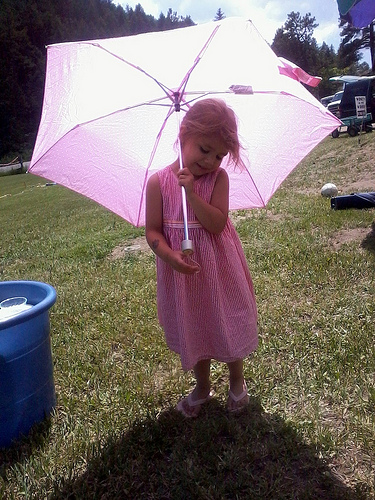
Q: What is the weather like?
A: It is overcast.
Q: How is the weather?
A: It is overcast.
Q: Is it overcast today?
A: Yes, it is overcast.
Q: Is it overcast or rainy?
A: It is overcast.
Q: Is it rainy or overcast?
A: It is overcast.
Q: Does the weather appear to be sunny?
A: No, it is overcast.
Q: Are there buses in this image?
A: No, there are no buses.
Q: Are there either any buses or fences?
A: No, there are no buses or fences.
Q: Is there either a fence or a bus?
A: No, there are no buses or fences.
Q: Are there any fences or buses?
A: No, there are no buses or fences.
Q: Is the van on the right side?
A: Yes, the van is on the right of the image.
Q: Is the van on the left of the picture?
A: No, the van is on the right of the image.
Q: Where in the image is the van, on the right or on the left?
A: The van is on the right of the image.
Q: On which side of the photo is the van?
A: The van is on the right of the image.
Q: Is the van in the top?
A: Yes, the van is in the top of the image.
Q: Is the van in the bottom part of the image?
A: No, the van is in the top of the image.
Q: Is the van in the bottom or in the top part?
A: The van is in the top of the image.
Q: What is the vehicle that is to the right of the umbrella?
A: The vehicle is a van.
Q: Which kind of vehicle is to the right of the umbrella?
A: The vehicle is a van.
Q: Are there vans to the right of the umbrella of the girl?
A: Yes, there is a van to the right of the umbrella.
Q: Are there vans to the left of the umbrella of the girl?
A: No, the van is to the right of the umbrella.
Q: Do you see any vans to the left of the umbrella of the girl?
A: No, the van is to the right of the umbrella.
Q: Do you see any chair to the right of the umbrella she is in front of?
A: No, there is a van to the right of the umbrella.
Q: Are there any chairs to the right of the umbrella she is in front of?
A: No, there is a van to the right of the umbrella.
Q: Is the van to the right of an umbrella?
A: Yes, the van is to the right of an umbrella.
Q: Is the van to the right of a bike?
A: No, the van is to the right of an umbrella.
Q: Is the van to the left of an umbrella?
A: No, the van is to the right of an umbrella.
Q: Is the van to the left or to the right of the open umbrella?
A: The van is to the right of the umbrella.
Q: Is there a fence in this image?
A: No, there are no fences.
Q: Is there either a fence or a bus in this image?
A: No, there are no fences or buses.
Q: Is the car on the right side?
A: Yes, the car is on the right of the image.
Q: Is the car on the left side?
A: No, the car is on the right of the image.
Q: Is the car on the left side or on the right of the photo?
A: The car is on the right of the image.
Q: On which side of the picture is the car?
A: The car is on the right of the image.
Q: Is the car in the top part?
A: Yes, the car is in the top of the image.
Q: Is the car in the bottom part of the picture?
A: No, the car is in the top of the image.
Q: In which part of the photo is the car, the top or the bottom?
A: The car is in the top of the image.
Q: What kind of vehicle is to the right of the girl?
A: The vehicle is a car.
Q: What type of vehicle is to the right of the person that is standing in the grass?
A: The vehicle is a car.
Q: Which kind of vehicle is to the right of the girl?
A: The vehicle is a car.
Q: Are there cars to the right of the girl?
A: Yes, there is a car to the right of the girl.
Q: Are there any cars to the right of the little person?
A: Yes, there is a car to the right of the girl.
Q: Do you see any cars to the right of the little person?
A: Yes, there is a car to the right of the girl.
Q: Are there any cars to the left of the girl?
A: No, the car is to the right of the girl.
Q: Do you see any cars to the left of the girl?
A: No, the car is to the right of the girl.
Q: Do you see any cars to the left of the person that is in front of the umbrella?
A: No, the car is to the right of the girl.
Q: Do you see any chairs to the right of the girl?
A: No, there is a car to the right of the girl.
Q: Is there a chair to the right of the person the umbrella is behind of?
A: No, there is a car to the right of the girl.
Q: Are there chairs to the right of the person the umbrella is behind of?
A: No, there is a car to the right of the girl.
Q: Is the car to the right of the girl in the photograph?
A: Yes, the car is to the right of the girl.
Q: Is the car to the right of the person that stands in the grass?
A: Yes, the car is to the right of the girl.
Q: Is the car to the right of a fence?
A: No, the car is to the right of the girl.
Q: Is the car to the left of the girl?
A: No, the car is to the right of the girl.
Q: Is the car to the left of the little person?
A: No, the car is to the right of the girl.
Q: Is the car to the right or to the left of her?
A: The car is to the right of the girl.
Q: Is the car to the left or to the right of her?
A: The car is to the right of the girl.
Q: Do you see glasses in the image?
A: No, there are no glasses.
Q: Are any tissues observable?
A: No, there are no tissues.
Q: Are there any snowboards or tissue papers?
A: No, there are no tissue papers or snowboards.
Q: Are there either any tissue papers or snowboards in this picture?
A: No, there are no tissue papers or snowboards.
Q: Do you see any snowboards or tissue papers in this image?
A: No, there are no tissue papers or snowboards.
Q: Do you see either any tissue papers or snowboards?
A: No, there are no tissue papers or snowboards.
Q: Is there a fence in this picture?
A: No, there are no fences.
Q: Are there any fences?
A: No, there are no fences.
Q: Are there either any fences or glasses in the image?
A: No, there are no fences or glasses.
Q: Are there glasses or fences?
A: No, there are no fences or glasses.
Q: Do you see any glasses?
A: No, there are no glasses.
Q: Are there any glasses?
A: No, there are no glasses.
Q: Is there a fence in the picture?
A: No, there are no fences.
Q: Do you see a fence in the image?
A: No, there are no fences.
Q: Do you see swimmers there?
A: No, there are no swimmers.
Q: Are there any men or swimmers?
A: No, there are no swimmers or men.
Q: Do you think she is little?
A: Yes, the girl is little.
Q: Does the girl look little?
A: Yes, the girl is little.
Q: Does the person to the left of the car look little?
A: Yes, the girl is little.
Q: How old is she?
A: The girl is little.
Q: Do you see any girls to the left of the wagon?
A: Yes, there is a girl to the left of the wagon.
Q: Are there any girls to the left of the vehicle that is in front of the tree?
A: Yes, there is a girl to the left of the wagon.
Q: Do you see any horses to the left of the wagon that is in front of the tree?
A: No, there is a girl to the left of the wagon.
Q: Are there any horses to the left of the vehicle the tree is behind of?
A: No, there is a girl to the left of the wagon.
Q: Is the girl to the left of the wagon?
A: Yes, the girl is to the left of the wagon.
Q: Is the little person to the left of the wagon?
A: Yes, the girl is to the left of the wagon.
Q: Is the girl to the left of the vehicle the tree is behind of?
A: Yes, the girl is to the left of the wagon.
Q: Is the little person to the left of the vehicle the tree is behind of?
A: Yes, the girl is to the left of the wagon.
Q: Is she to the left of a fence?
A: No, the girl is to the left of the wagon.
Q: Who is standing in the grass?
A: The girl is standing in the grass.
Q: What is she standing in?
A: The girl is standing in the grass.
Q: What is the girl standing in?
A: The girl is standing in the grass.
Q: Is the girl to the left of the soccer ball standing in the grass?
A: Yes, the girl is standing in the grass.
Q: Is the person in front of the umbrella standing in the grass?
A: Yes, the girl is standing in the grass.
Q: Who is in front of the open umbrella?
A: The girl is in front of the umbrella.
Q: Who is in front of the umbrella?
A: The girl is in front of the umbrella.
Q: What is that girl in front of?
A: The girl is in front of the umbrella.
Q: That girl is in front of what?
A: The girl is in front of the umbrella.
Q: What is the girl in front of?
A: The girl is in front of the umbrella.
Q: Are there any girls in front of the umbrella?
A: Yes, there is a girl in front of the umbrella.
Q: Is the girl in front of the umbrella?
A: Yes, the girl is in front of the umbrella.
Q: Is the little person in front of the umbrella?
A: Yes, the girl is in front of the umbrella.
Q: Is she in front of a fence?
A: No, the girl is in front of the umbrella.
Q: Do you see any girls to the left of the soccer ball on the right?
A: Yes, there is a girl to the left of the soccer ball.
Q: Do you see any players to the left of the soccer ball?
A: No, there is a girl to the left of the soccer ball.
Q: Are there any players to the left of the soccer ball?
A: No, there is a girl to the left of the soccer ball.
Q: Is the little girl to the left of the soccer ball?
A: Yes, the girl is to the left of the soccer ball.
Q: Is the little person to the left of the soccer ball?
A: Yes, the girl is to the left of the soccer ball.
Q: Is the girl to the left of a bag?
A: No, the girl is to the left of the soccer ball.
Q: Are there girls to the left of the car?
A: Yes, there is a girl to the left of the car.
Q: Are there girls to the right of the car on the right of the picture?
A: No, the girl is to the left of the car.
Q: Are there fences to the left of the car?
A: No, there is a girl to the left of the car.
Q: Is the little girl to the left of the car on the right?
A: Yes, the girl is to the left of the car.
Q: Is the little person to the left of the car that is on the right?
A: Yes, the girl is to the left of the car.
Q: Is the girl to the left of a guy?
A: No, the girl is to the left of the car.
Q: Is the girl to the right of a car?
A: No, the girl is to the left of a car.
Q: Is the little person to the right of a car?
A: No, the girl is to the left of a car.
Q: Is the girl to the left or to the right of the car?
A: The girl is to the left of the car.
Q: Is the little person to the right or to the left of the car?
A: The girl is to the left of the car.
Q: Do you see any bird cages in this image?
A: No, there are no bird cages.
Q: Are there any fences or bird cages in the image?
A: No, there are no bird cages or fences.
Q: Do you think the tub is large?
A: Yes, the tub is large.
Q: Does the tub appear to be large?
A: Yes, the tub is large.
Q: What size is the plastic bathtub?
A: The bathtub is large.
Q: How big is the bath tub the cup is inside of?
A: The bathtub is large.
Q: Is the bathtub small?
A: No, the bathtub is large.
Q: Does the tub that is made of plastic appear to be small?
A: No, the bathtub is large.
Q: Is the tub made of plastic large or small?
A: The bathtub is large.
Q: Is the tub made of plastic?
A: Yes, the tub is made of plastic.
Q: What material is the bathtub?
A: The bathtub is made of plastic.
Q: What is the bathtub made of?
A: The bathtub is made of plastic.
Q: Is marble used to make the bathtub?
A: No, the bathtub is made of plastic.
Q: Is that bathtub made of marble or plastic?
A: The bathtub is made of plastic.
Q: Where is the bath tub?
A: The bath tub is on the grass.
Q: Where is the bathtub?
A: The bath tub is on the grass.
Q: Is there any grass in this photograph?
A: Yes, there is grass.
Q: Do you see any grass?
A: Yes, there is grass.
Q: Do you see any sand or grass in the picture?
A: Yes, there is grass.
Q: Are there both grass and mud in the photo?
A: No, there is grass but no mud.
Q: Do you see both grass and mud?
A: No, there is grass but no mud.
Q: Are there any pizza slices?
A: No, there are no pizza slices.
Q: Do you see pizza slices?
A: No, there are no pizza slices.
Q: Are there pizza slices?
A: No, there are no pizza slices.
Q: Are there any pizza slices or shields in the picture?
A: No, there are no pizza slices or shields.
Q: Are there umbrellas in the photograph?
A: Yes, there is an umbrella.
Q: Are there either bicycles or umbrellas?
A: Yes, there is an umbrella.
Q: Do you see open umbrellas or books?
A: Yes, there is an open umbrella.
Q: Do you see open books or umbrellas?
A: Yes, there is an open umbrella.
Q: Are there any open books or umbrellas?
A: Yes, there is an open umbrella.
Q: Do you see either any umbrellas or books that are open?
A: Yes, the umbrella is open.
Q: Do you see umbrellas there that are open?
A: Yes, there is an open umbrella.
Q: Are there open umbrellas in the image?
A: Yes, there is an open umbrella.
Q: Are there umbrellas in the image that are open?
A: Yes, there is an umbrella that is open.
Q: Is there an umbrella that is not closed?
A: Yes, there is a open umbrella.